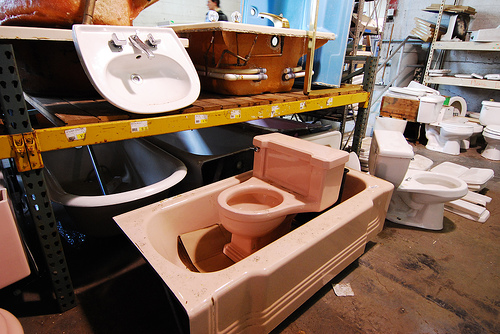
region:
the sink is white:
[79, 28, 219, 108]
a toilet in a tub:
[100, 113, 389, 320]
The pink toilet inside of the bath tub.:
[217, 130, 344, 227]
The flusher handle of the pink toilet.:
[247, 145, 262, 152]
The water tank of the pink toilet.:
[255, 141, 347, 206]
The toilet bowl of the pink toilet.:
[217, 188, 288, 232]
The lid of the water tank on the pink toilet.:
[257, 134, 356, 168]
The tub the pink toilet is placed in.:
[112, 144, 392, 332]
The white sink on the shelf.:
[67, 18, 197, 110]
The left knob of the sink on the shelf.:
[112, 30, 131, 47]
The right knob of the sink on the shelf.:
[150, 32, 162, 49]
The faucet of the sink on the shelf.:
[135, 28, 153, 60]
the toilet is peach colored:
[216, 130, 349, 262]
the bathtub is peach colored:
[113, 176, 390, 331]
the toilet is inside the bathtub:
[112, 129, 394, 332]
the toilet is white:
[371, 127, 470, 232]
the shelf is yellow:
[1, 90, 369, 160]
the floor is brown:
[278, 225, 498, 331]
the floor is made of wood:
[286, 214, 498, 332]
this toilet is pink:
[0, 185, 32, 330]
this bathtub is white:
[42, 145, 190, 209]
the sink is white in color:
[73, 19, 199, 111]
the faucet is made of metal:
[130, 29, 156, 59]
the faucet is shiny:
[131, 30, 153, 58]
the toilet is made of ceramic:
[220, 129, 348, 270]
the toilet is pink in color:
[223, 132, 347, 264]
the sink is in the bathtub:
[117, 134, 392, 328]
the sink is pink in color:
[113, 129, 391, 329]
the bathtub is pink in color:
[118, 134, 398, 330]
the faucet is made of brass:
[260, 7, 288, 29]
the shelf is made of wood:
[3, 79, 365, 154]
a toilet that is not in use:
[209, 131, 336, 239]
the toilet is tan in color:
[217, 132, 356, 227]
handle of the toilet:
[248, 140, 265, 155]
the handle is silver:
[248, 145, 262, 153]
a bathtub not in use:
[121, 145, 391, 315]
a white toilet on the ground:
[368, 131, 460, 227]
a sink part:
[73, 26, 202, 109]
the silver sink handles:
[106, 35, 170, 55]